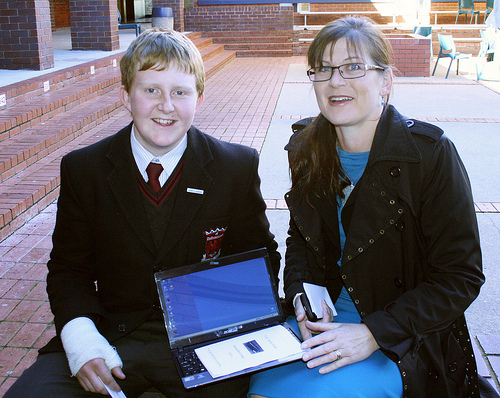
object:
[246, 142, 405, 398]
dress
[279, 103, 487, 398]
jacket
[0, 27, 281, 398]
boy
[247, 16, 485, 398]
woman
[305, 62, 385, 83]
glasses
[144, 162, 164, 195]
tie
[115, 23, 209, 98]
hair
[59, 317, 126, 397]
hand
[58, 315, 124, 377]
cast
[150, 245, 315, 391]
laptop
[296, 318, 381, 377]
hand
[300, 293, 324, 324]
cell phone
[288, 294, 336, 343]
hand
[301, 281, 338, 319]
envelope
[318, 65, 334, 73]
eye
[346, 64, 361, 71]
eye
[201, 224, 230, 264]
insignia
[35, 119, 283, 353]
coat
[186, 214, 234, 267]
pocket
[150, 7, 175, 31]
trash can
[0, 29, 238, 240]
steps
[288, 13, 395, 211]
hair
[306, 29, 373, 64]
bangs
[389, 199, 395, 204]
eyelet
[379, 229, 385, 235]
eyelet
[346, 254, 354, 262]
eyelet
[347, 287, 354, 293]
eyelet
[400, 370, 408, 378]
eyelet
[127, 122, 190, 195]
shirt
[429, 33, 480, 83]
patio chair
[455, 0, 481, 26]
patio chair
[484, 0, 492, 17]
patio chair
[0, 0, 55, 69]
column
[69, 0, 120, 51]
column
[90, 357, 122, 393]
finger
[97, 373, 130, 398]
splint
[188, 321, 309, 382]
pamphlet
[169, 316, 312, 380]
keyboard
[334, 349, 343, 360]
ring finger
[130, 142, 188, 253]
vest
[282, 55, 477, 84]
cement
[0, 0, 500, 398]
patio